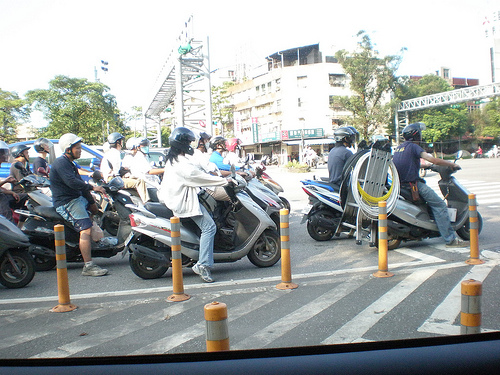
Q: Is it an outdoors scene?
A: Yes, it is outdoors.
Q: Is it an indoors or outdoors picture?
A: It is outdoors.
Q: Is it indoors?
A: No, it is outdoors.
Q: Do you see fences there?
A: No, there are no fences.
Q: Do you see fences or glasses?
A: No, there are no fences or glasses.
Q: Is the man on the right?
A: Yes, the man is on the right of the image.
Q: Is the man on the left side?
A: No, the man is on the right of the image.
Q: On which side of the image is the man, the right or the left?
A: The man is on the right of the image.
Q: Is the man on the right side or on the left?
A: The man is on the right of the image.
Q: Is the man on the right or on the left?
A: The man is on the right of the image.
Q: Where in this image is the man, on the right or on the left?
A: The man is on the right of the image.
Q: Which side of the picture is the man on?
A: The man is on the right of the image.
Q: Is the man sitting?
A: Yes, the man is sitting.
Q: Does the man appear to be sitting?
A: Yes, the man is sitting.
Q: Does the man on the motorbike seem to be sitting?
A: Yes, the man is sitting.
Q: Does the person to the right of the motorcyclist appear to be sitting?
A: Yes, the man is sitting.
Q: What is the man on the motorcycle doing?
A: The man is sitting.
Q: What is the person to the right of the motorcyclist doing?
A: The man is sitting.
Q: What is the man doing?
A: The man is sitting.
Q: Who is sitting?
A: The man is sitting.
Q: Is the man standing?
A: No, the man is sitting.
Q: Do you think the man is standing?
A: No, the man is sitting.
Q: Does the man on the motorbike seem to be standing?
A: No, the man is sitting.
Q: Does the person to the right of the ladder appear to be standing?
A: No, the man is sitting.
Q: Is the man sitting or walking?
A: The man is sitting.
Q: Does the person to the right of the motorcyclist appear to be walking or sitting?
A: The man is sitting.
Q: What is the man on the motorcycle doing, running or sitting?
A: The man is sitting.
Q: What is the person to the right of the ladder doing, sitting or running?
A: The man is sitting.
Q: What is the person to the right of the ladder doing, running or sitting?
A: The man is sitting.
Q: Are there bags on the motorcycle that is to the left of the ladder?
A: No, there is a man on the motorbike.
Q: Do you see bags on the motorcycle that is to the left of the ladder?
A: No, there is a man on the motorbike.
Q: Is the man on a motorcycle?
A: Yes, the man is on a motorcycle.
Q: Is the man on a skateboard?
A: No, the man is on a motorcycle.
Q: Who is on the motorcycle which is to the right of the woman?
A: The man is on the motorbike.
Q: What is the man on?
A: The man is on the motorbike.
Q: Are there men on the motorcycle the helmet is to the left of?
A: Yes, there is a man on the motorcycle.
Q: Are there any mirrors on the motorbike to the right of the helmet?
A: No, there is a man on the motorbike.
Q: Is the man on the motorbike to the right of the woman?
A: Yes, the man is on the motorbike.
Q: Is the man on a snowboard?
A: No, the man is on the motorbike.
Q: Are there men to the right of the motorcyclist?
A: Yes, there is a man to the right of the motorcyclist.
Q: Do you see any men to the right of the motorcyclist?
A: Yes, there is a man to the right of the motorcyclist.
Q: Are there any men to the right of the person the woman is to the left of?
A: Yes, there is a man to the right of the motorcyclist.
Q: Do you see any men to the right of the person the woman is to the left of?
A: Yes, there is a man to the right of the motorcyclist.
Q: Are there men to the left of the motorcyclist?
A: No, the man is to the right of the motorcyclist.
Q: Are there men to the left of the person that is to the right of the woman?
A: No, the man is to the right of the motorcyclist.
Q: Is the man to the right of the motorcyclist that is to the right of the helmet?
A: Yes, the man is to the right of the motorcyclist.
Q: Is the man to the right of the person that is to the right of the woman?
A: Yes, the man is to the right of the motorcyclist.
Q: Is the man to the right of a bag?
A: No, the man is to the right of the motorcyclist.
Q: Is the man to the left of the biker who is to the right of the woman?
A: No, the man is to the right of the biker.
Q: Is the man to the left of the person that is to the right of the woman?
A: No, the man is to the right of the biker.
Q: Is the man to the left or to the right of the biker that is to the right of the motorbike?
A: The man is to the right of the motorcyclist.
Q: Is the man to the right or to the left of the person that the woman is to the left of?
A: The man is to the right of the motorcyclist.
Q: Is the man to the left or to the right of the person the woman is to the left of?
A: The man is to the right of the motorcyclist.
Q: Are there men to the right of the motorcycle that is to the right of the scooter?
A: Yes, there is a man to the right of the motorcycle.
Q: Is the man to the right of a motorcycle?
A: Yes, the man is to the right of a motorcycle.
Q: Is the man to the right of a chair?
A: No, the man is to the right of a motorcycle.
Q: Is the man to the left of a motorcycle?
A: No, the man is to the right of a motorcycle.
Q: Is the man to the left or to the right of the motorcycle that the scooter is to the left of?
A: The man is to the right of the motorbike.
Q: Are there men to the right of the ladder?
A: Yes, there is a man to the right of the ladder.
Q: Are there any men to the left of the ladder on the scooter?
A: No, the man is to the right of the ladder.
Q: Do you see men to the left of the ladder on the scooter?
A: No, the man is to the right of the ladder.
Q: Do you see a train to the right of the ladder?
A: No, there is a man to the right of the ladder.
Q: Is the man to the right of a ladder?
A: Yes, the man is to the right of a ladder.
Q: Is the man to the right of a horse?
A: No, the man is to the right of a ladder.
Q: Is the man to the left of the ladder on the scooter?
A: No, the man is to the right of the ladder.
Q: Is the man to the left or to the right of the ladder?
A: The man is to the right of the ladder.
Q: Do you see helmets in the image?
A: Yes, there is a helmet.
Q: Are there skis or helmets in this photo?
A: Yes, there is a helmet.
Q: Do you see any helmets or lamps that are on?
A: Yes, the helmet is on.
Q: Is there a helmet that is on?
A: Yes, there is a helmet that is on.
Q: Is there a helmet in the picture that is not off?
A: Yes, there is a helmet that is on.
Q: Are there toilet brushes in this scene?
A: No, there are no toilet brushes.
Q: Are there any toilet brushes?
A: No, there are no toilet brushes.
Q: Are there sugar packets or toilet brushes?
A: No, there are no toilet brushes or sugar packets.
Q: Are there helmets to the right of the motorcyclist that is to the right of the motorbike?
A: Yes, there is a helmet to the right of the motorcyclist.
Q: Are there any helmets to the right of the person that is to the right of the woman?
A: Yes, there is a helmet to the right of the motorcyclist.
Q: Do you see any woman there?
A: Yes, there is a woman.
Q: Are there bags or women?
A: Yes, there is a woman.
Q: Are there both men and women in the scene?
A: Yes, there are both a woman and a man.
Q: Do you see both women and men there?
A: Yes, there are both a woman and a man.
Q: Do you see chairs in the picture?
A: No, there are no chairs.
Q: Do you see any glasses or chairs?
A: No, there are no chairs or glasses.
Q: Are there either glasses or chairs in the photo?
A: No, there are no chairs or glasses.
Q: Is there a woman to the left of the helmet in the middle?
A: Yes, there is a woman to the left of the helmet.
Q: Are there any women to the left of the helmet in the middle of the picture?
A: Yes, there is a woman to the left of the helmet.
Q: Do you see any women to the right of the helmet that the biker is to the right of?
A: No, the woman is to the left of the helmet.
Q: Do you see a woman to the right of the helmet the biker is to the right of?
A: No, the woman is to the left of the helmet.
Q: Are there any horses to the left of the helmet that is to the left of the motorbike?
A: No, there is a woman to the left of the helmet.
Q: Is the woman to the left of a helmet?
A: Yes, the woman is to the left of a helmet.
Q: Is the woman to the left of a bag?
A: No, the woman is to the left of a helmet.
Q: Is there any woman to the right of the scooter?
A: Yes, there is a woman to the right of the scooter.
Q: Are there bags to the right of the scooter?
A: No, there is a woman to the right of the scooter.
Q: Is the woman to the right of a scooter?
A: Yes, the woman is to the right of a scooter.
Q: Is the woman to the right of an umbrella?
A: No, the woman is to the right of a scooter.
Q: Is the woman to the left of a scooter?
A: No, the woman is to the right of a scooter.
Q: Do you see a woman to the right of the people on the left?
A: Yes, there is a woman to the right of the people.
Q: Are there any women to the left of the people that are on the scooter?
A: No, the woman is to the right of the people.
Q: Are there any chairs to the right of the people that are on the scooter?
A: No, there is a woman to the right of the people.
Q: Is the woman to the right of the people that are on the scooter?
A: Yes, the woman is to the right of the people.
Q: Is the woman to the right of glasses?
A: No, the woman is to the right of the people.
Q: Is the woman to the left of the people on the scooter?
A: No, the woman is to the right of the people.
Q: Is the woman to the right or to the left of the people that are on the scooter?
A: The woman is to the right of the people.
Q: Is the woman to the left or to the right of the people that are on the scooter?
A: The woman is to the right of the people.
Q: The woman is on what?
A: The woman is on the motorcycle.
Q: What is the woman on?
A: The woman is on the motorcycle.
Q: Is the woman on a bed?
A: No, the woman is on the motorbike.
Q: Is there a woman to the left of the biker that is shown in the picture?
A: Yes, there is a woman to the left of the biker.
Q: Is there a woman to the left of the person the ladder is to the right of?
A: Yes, there is a woman to the left of the biker.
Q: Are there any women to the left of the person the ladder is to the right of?
A: Yes, there is a woman to the left of the biker.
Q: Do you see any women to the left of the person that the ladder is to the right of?
A: Yes, there is a woman to the left of the biker.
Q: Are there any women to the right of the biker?
A: No, the woman is to the left of the biker.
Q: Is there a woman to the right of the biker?
A: No, the woman is to the left of the biker.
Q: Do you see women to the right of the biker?
A: No, the woman is to the left of the biker.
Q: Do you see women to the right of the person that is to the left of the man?
A: No, the woman is to the left of the biker.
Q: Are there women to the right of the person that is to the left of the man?
A: No, the woman is to the left of the biker.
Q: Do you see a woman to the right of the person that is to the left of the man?
A: No, the woman is to the left of the biker.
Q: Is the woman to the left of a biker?
A: Yes, the woman is to the left of a biker.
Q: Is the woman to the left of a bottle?
A: No, the woman is to the left of a biker.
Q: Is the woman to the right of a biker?
A: No, the woman is to the left of a biker.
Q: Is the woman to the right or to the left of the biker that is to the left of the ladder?
A: The woman is to the left of the motorcyclist.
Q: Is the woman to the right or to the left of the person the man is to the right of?
A: The woman is to the left of the motorcyclist.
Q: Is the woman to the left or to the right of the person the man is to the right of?
A: The woman is to the left of the motorcyclist.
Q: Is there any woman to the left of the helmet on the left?
A: No, the woman is to the right of the helmet.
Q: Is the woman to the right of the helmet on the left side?
A: Yes, the woman is to the right of the helmet.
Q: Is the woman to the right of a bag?
A: No, the woman is to the right of the helmet.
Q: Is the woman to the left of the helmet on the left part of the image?
A: No, the woman is to the right of the helmet.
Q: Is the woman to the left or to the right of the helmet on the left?
A: The woman is to the right of the helmet.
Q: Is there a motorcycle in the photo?
A: Yes, there is a motorcycle.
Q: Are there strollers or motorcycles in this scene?
A: Yes, there is a motorcycle.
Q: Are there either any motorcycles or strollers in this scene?
A: Yes, there is a motorcycle.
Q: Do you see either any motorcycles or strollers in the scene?
A: Yes, there is a motorcycle.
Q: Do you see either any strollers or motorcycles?
A: Yes, there is a motorcycle.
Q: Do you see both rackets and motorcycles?
A: No, there is a motorcycle but no rackets.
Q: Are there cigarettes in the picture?
A: No, there are no cigarettes.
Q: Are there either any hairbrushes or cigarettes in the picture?
A: No, there are no cigarettes or hairbrushes.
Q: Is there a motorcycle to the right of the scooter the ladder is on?
A: Yes, there is a motorcycle to the right of the scooter.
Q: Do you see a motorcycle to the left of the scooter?
A: No, the motorcycle is to the right of the scooter.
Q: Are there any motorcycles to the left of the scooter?
A: No, the motorcycle is to the right of the scooter.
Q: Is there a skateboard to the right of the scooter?
A: No, there is a motorcycle to the right of the scooter.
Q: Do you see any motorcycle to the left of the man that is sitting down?
A: Yes, there is a motorcycle to the left of the man.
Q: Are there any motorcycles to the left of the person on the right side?
A: Yes, there is a motorcycle to the left of the man.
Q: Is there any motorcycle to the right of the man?
A: No, the motorcycle is to the left of the man.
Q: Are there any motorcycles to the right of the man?
A: No, the motorcycle is to the left of the man.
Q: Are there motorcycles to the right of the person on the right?
A: No, the motorcycle is to the left of the man.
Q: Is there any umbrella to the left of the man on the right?
A: No, there is a motorcycle to the left of the man.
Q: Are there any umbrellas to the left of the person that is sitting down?
A: No, there is a motorcycle to the left of the man.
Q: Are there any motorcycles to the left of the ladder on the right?
A: Yes, there is a motorcycle to the left of the ladder.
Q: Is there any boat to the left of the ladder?
A: No, there is a motorcycle to the left of the ladder.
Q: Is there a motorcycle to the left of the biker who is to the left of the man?
A: Yes, there is a motorcycle to the left of the biker.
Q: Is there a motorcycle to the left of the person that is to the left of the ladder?
A: Yes, there is a motorcycle to the left of the biker.